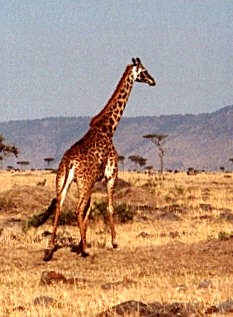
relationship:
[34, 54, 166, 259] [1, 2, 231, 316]
giraffe in wild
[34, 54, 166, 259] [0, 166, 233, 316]
giraffe in plants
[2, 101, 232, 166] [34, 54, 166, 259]
hills behind giraffe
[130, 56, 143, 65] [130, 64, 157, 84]
knobs on head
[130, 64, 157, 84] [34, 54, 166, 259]
head of giraffe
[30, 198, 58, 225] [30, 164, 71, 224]
hair on tail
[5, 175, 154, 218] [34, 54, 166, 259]
dirt mounds behind giraffe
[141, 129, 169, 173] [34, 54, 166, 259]
tree behind giraffe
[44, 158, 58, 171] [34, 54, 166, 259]
tree behind giraffe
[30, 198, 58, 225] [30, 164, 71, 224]
hair on end of tail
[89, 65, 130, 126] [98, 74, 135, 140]
mane on neck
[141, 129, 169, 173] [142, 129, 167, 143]
tree has leaves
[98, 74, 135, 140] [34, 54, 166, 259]
neck of giraffe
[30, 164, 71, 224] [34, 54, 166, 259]
tail of giraffe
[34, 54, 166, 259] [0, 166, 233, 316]
giraffe walking in plants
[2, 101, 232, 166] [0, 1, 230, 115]
hills below sky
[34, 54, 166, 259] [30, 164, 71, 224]
giraffe wagging h tail